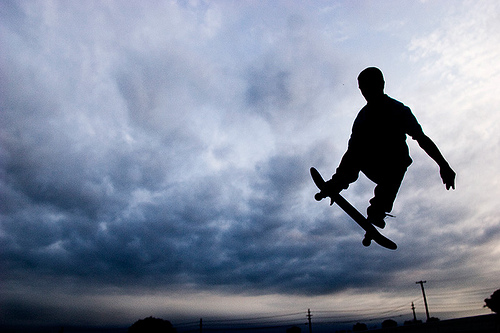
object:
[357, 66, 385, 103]
head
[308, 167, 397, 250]
board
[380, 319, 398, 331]
tree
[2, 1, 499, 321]
sky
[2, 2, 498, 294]
clouds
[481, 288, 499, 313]
tree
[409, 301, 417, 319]
pole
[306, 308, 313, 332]
pole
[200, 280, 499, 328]
lines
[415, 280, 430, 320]
poles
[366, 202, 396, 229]
untied shoe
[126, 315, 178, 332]
tree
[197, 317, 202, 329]
poles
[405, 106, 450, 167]
arm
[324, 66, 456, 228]
boy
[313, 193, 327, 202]
wheel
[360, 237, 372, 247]
wheel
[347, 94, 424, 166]
shirt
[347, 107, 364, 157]
sleeve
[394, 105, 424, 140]
sleeve